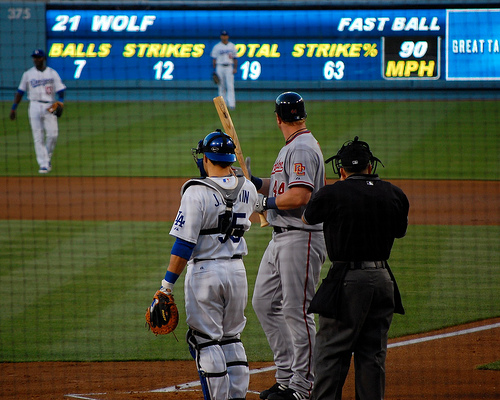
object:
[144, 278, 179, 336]
carton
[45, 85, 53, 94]
panda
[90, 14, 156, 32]
wolf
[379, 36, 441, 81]
sign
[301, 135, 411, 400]
umpire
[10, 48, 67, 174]
catcher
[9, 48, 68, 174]
player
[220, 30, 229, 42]
head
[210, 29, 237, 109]
man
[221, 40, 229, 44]
neck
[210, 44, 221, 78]
arm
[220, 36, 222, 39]
ear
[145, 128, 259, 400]
he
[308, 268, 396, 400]
pant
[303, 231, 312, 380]
stripe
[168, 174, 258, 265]
shirt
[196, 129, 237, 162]
helmet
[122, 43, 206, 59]
word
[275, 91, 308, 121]
helmet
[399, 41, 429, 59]
number